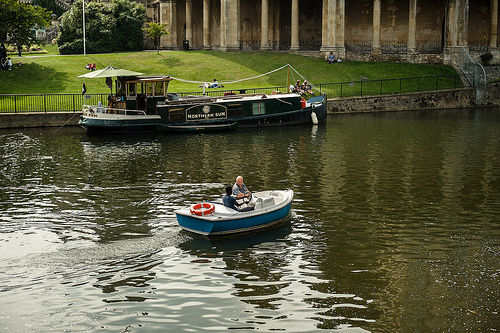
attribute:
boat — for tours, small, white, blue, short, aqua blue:
[176, 188, 293, 237]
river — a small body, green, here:
[2, 104, 499, 332]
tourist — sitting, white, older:
[233, 175, 248, 198]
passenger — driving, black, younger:
[222, 186, 250, 211]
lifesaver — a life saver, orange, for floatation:
[189, 203, 213, 217]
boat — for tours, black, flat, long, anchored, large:
[78, 64, 328, 132]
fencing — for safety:
[0, 72, 474, 113]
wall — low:
[0, 86, 475, 134]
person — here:
[328, 52, 337, 63]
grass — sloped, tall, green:
[0, 48, 462, 114]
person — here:
[199, 78, 216, 89]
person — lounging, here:
[85, 63, 96, 69]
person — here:
[4, 57, 11, 69]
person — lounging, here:
[300, 81, 315, 95]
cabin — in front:
[114, 74, 173, 114]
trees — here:
[0, 0, 56, 62]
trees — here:
[141, 21, 169, 55]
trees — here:
[51, 0, 157, 56]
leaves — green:
[142, 20, 171, 38]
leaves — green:
[0, 0, 53, 49]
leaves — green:
[54, 7, 84, 54]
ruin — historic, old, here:
[141, 2, 499, 64]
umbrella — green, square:
[78, 65, 145, 77]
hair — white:
[236, 175, 244, 181]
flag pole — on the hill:
[82, 0, 87, 55]